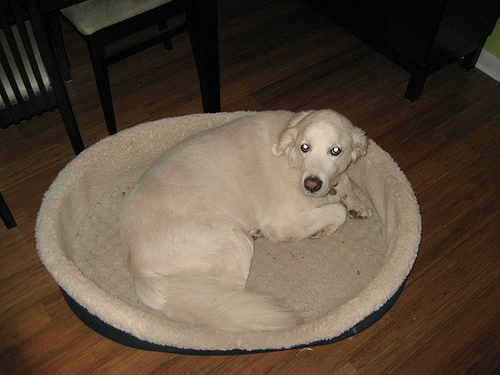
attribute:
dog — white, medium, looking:
[113, 118, 363, 317]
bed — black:
[30, 115, 421, 349]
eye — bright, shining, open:
[299, 143, 312, 153]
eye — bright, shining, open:
[330, 146, 345, 158]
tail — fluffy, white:
[161, 289, 302, 327]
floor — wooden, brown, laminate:
[4, 10, 498, 374]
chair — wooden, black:
[49, 5, 239, 105]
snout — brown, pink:
[296, 168, 331, 197]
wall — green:
[486, 26, 499, 55]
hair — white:
[145, 233, 164, 247]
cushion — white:
[69, 2, 169, 29]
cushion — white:
[2, 20, 49, 92]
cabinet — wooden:
[326, 8, 496, 87]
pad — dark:
[349, 208, 358, 216]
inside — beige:
[62, 194, 113, 254]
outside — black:
[63, 299, 119, 335]